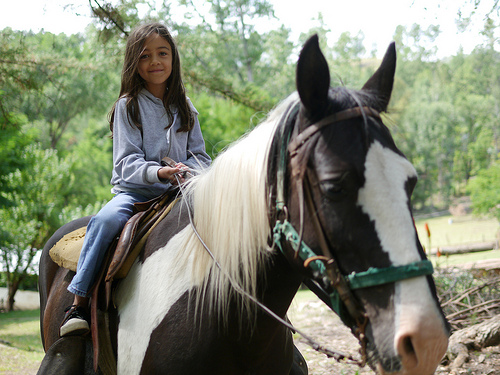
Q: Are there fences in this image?
A: No, there are no fences.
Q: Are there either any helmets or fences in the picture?
A: No, there are no fences or helmets.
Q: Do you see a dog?
A: No, there are no dogs.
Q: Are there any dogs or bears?
A: No, there are no dogs or bears.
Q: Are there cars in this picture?
A: No, there are no cars.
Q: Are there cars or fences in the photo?
A: No, there are no cars or fences.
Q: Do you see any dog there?
A: No, there are no dogs.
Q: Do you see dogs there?
A: No, there are no dogs.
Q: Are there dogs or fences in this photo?
A: No, there are no dogs or fences.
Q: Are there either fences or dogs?
A: No, there are no dogs or fences.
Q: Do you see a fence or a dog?
A: No, there are no dogs or fences.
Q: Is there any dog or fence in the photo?
A: No, there are no dogs or fences.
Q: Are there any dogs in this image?
A: No, there are no dogs.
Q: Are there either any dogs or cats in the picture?
A: No, there are no dogs or cats.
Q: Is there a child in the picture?
A: Yes, there is a child.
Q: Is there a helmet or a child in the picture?
A: Yes, there is a child.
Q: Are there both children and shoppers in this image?
A: No, there is a child but no shoppers.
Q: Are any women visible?
A: No, there are no women.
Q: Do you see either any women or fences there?
A: No, there are no women or fences.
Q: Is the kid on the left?
A: Yes, the kid is on the left of the image.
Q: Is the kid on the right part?
A: No, the kid is on the left of the image.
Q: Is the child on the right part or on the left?
A: The child is on the left of the image.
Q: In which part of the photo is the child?
A: The child is on the left of the image.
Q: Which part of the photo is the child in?
A: The child is on the left of the image.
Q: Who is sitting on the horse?
A: The child is sitting on the horse.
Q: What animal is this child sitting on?
A: The child is sitting on the horse.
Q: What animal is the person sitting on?
A: The kid is sitting on the horse.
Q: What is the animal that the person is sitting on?
A: The animal is a horse.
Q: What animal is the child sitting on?
A: The kid is sitting on the horse.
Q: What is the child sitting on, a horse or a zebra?
A: The child is sitting on a horse.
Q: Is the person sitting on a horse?
A: Yes, the kid is sitting on a horse.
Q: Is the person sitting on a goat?
A: No, the child is sitting on a horse.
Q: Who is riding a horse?
A: The kid is riding a horse.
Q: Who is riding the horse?
A: The kid is riding a horse.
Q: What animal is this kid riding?
A: The kid is riding a horse.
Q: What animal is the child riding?
A: The kid is riding a horse.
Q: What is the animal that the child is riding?
A: The animal is a horse.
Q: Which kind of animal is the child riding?
A: The child is riding a horse.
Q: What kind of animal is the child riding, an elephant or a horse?
A: The child is riding a horse.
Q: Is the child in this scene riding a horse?
A: Yes, the child is riding a horse.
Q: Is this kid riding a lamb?
A: No, the kid is riding a horse.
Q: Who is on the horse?
A: The kid is on the horse.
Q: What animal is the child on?
A: The child is on the horse.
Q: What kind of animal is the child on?
A: The child is on the horse.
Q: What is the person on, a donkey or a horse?
A: The child is on a horse.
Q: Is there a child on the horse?
A: Yes, there is a child on the horse.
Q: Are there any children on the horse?
A: Yes, there is a child on the horse.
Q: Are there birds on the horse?
A: No, there is a child on the horse.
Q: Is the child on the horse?
A: Yes, the child is on the horse.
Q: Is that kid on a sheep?
A: No, the kid is on the horse.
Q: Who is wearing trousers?
A: The kid is wearing trousers.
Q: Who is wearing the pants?
A: The kid is wearing trousers.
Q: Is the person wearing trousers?
A: Yes, the child is wearing trousers.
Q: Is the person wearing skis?
A: No, the kid is wearing trousers.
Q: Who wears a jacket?
A: The kid wears a jacket.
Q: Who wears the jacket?
A: The kid wears a jacket.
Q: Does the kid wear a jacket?
A: Yes, the kid wears a jacket.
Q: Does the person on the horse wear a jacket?
A: Yes, the kid wears a jacket.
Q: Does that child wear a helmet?
A: No, the child wears a jacket.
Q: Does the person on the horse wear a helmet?
A: No, the child wears a jacket.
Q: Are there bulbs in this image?
A: No, there are no bulbs.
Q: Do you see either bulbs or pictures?
A: No, there are no bulbs or pictures.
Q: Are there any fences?
A: No, there are no fences.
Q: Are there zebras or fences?
A: No, there are no fences or zebras.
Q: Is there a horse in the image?
A: Yes, there is a horse.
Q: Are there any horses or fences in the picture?
A: Yes, there is a horse.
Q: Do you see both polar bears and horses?
A: No, there is a horse but no polar bears.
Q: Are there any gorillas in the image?
A: No, there are no gorillas.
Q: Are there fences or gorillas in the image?
A: No, there are no gorillas or fences.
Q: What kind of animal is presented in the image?
A: The animal is a horse.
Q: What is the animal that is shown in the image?
A: The animal is a horse.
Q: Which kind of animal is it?
A: The animal is a horse.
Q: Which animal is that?
A: This is a horse.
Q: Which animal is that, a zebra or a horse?
A: This is a horse.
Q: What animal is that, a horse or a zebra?
A: This is a horse.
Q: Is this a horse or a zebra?
A: This is a horse.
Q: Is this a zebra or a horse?
A: This is a horse.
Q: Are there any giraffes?
A: No, there are no giraffes.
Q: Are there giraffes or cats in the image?
A: No, there are no giraffes or cats.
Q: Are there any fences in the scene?
A: No, there are no fences.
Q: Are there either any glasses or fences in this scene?
A: No, there are no fences or glasses.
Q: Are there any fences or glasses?
A: No, there are no fences or glasses.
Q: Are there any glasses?
A: No, there are no glasses.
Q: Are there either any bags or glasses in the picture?
A: No, there are no glasses or bags.